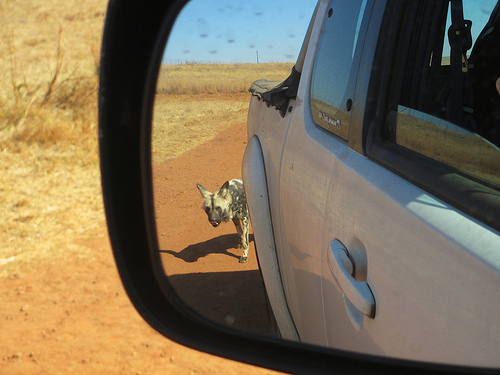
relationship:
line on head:
[205, 188, 228, 210] [183, 167, 241, 235]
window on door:
[274, 0, 372, 149] [256, 0, 375, 345]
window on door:
[396, 103, 500, 194] [314, 11, 484, 359]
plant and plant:
[0, 24, 101, 163] [0, 24, 101, 163]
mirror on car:
[98, 6, 481, 373] [235, 0, 453, 374]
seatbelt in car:
[442, 0, 481, 117] [231, 3, 499, 367]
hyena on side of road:
[184, 148, 267, 277] [1, 113, 238, 372]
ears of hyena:
[187, 171, 237, 200] [192, 174, 261, 275]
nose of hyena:
[203, 218, 223, 228] [184, 163, 261, 266]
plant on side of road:
[1, 50, 92, 163] [0, 103, 262, 370]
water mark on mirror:
[159, 0, 307, 101] [144, 0, 500, 373]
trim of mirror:
[83, 0, 154, 321] [152, 2, 478, 357]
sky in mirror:
[160, 0, 309, 74] [98, 6, 481, 373]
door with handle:
[326, 22, 484, 351] [321, 234, 381, 324]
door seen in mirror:
[326, 22, 484, 351] [98, 6, 481, 373]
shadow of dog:
[165, 232, 245, 265] [197, 174, 262, 264]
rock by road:
[7, 268, 21, 282] [9, 207, 227, 373]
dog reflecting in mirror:
[197, 174, 262, 264] [152, 2, 478, 357]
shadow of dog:
[165, 232, 245, 265] [194, 177, 254, 263]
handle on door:
[328, 238, 374, 316] [334, 1, 482, 349]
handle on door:
[328, 238, 374, 316] [314, 11, 484, 359]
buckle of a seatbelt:
[452, 23, 470, 53] [445, 0, 472, 126]